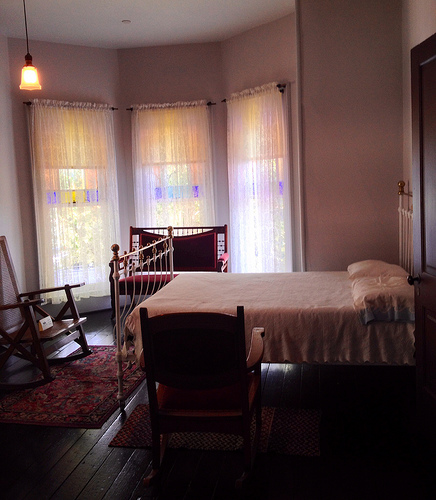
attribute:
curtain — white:
[25, 102, 302, 290]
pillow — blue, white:
[352, 274, 418, 325]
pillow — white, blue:
[346, 256, 407, 277]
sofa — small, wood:
[110, 214, 227, 321]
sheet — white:
[135, 257, 413, 369]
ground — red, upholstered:
[410, 113, 433, 137]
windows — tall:
[19, 91, 124, 308]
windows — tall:
[122, 96, 217, 236]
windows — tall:
[216, 79, 296, 275]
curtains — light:
[21, 92, 128, 306]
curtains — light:
[125, 95, 220, 235]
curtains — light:
[219, 80, 296, 268]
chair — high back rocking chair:
[1, 224, 106, 380]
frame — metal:
[108, 226, 174, 410]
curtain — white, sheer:
[213, 100, 327, 337]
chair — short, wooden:
[126, 300, 284, 483]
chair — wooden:
[2, 230, 98, 395]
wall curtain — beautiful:
[235, 83, 341, 269]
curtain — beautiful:
[36, 96, 125, 309]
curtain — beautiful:
[122, 95, 216, 231]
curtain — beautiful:
[219, 79, 298, 273]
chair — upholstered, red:
[108, 218, 231, 300]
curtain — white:
[128, 95, 217, 237]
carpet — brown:
[104, 397, 332, 462]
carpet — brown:
[0, 341, 145, 434]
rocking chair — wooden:
[0, 236, 92, 392]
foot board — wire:
[110, 226, 174, 411]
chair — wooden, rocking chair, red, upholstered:
[138, 302, 265, 487]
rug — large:
[0, 343, 145, 425]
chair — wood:
[127, 301, 275, 491]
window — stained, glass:
[39, 167, 105, 205]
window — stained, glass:
[140, 162, 206, 199]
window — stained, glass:
[237, 153, 286, 191]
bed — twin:
[124, 258, 415, 367]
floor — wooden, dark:
[49, 442, 97, 476]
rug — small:
[104, 381, 331, 460]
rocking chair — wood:
[3, 250, 104, 402]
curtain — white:
[31, 98, 121, 309]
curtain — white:
[220, 84, 293, 272]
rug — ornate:
[66, 370, 105, 425]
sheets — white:
[124, 270, 414, 369]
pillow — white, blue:
[352, 273, 413, 322]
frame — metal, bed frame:
[110, 178, 412, 412]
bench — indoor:
[109, 223, 229, 327]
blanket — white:
[123, 257, 414, 365]